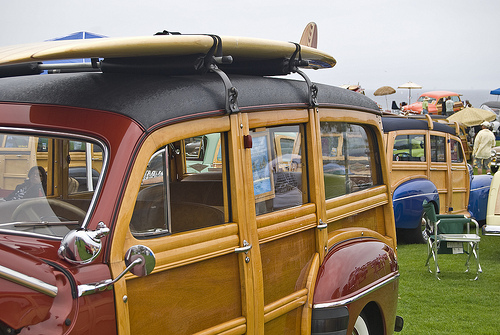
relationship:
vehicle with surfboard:
[7, 75, 396, 330] [4, 22, 343, 73]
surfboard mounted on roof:
[4, 22, 343, 73] [4, 77, 391, 109]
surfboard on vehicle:
[4, 22, 343, 73] [7, 75, 396, 330]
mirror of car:
[127, 245, 158, 274] [7, 75, 396, 330]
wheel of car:
[13, 194, 84, 232] [7, 75, 396, 330]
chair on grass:
[424, 203, 483, 280] [403, 245, 499, 331]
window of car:
[253, 126, 310, 215] [7, 75, 396, 330]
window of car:
[135, 149, 171, 236] [7, 75, 396, 330]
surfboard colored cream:
[4, 22, 343, 73] [3, 23, 337, 65]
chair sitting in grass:
[424, 203, 483, 280] [403, 245, 499, 331]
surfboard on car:
[4, 22, 343, 73] [7, 75, 396, 330]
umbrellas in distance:
[373, 78, 499, 102] [351, 69, 496, 116]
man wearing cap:
[473, 121, 496, 176] [480, 119, 491, 129]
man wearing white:
[473, 121, 496, 176] [473, 118, 497, 160]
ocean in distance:
[368, 88, 498, 110] [351, 69, 496, 116]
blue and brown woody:
[393, 165, 491, 228] [388, 115, 493, 241]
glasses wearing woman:
[27, 171, 43, 178] [10, 166, 48, 196]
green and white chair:
[422, 200, 471, 257] [424, 203, 483, 280]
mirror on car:
[58, 230, 101, 266] [7, 75, 396, 330]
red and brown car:
[6, 104, 398, 335] [7, 75, 396, 330]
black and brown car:
[381, 120, 456, 132] [388, 115, 493, 241]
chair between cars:
[424, 203, 483, 280] [7, 75, 396, 330]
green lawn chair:
[422, 200, 471, 257] [424, 203, 483, 280]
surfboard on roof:
[4, 22, 343, 73] [4, 77, 391, 109]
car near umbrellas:
[406, 92, 464, 113] [373, 78, 499, 102]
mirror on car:
[127, 245, 158, 274] [7, 75, 396, 330]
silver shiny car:
[122, 245, 160, 276] [7, 75, 396, 330]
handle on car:
[230, 238, 251, 258] [7, 75, 396, 330]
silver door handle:
[319, 215, 329, 229] [317, 215, 329, 232]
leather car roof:
[1, 74, 383, 128] [4, 77, 391, 109]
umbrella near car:
[489, 87, 499, 96] [406, 92, 464, 113]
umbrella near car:
[397, 81, 422, 92] [406, 92, 464, 113]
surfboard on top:
[4, 22, 343, 73] [3, 71, 385, 126]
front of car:
[1, 72, 110, 332] [7, 75, 396, 330]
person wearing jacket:
[473, 118, 499, 169] [474, 129, 495, 161]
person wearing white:
[473, 118, 499, 169] [473, 118, 497, 160]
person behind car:
[10, 166, 48, 196] [7, 75, 396, 330]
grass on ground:
[403, 245, 499, 331] [409, 260, 481, 327]